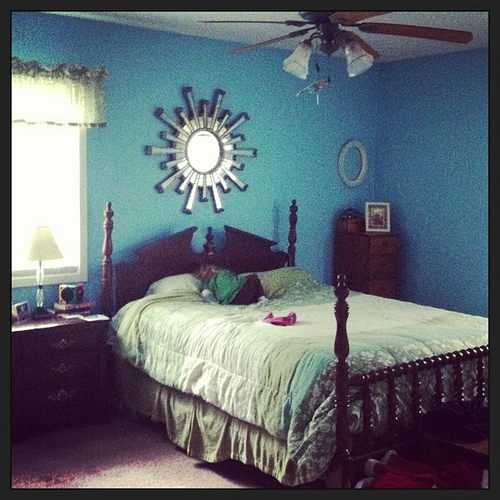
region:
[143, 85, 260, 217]
sun mirror on the wall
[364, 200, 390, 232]
picture frame on the dresser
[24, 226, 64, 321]
light on the dresser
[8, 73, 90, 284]
window in the bedroom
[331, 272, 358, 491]
wood post on the corner of the bed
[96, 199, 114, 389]
wood post on the corner of the bed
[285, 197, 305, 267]
wood post on the corner of the bed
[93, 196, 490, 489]
wood framed bed in a bedroom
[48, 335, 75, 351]
a handle on the dresser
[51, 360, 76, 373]
a handle on the dresser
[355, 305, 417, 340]
a comforter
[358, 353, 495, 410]
railing on the bed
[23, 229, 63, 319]
a lamp on the night stand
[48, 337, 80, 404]
handles on the dresser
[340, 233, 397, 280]
a small dresser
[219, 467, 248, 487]
a shadow under the bed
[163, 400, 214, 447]
the bed skirt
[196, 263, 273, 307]
a person sleeping on the bed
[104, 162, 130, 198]
the wall is blue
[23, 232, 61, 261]
a white lamp shade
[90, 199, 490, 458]
A brown bed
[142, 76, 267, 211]
A decorative mirror over bed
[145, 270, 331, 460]
A light colored bedspread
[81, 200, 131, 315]
A brown bed post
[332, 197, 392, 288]
A wooden cabinet on right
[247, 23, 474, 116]
A brown ceiling fan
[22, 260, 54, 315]
A clear lamp base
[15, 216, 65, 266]
A white lamp shade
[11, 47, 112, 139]
A light colored valance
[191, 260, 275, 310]
A small child on bed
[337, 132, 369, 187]
mirror on the wall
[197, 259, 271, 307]
child on the bed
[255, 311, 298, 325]
clothing on the bed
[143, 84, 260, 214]
mirror on the wall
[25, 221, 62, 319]
lamp on the night stand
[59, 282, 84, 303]
clock on the night stand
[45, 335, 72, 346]
handle on the drawer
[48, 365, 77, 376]
handle on the drawer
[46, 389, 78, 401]
handle on the drawer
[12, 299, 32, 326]
picture on night stand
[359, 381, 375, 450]
brown wooden post on footboard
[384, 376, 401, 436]
brown wooden post on footboard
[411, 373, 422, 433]
brown wooden post on footboard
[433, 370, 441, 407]
brown wooden post on footboard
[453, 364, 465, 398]
brown wooden post on footboard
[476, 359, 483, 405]
brown wooden post on footboard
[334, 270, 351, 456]
brown wooden post on footboard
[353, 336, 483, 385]
brown wooden post on footboard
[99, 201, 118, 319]
brown wooden post on headboard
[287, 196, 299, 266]
brown wooden post on headboard